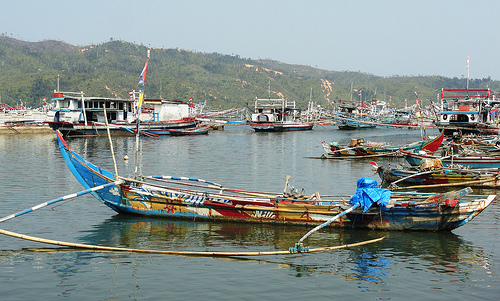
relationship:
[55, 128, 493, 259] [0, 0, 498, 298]
boat going down on water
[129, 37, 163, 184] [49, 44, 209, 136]
colorful flag on boat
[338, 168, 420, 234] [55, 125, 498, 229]
an outrigger on boat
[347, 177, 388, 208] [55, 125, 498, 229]
tarp covering portion of boat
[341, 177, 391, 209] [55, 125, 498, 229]
tarp on boat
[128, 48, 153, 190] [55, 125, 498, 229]
flag pole on boat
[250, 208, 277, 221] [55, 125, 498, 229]
word nille written on boat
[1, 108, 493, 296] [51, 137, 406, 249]
water around boat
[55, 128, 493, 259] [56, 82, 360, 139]
boat going down in background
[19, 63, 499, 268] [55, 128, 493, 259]
many boats behind boat going down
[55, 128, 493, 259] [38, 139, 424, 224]
boat going down in foreground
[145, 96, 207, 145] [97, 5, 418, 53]
hazy sky in background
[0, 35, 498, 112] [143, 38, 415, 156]
mountains covered in distance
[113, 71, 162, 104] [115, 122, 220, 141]
flag on small canoe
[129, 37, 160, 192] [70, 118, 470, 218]
flag pole on boat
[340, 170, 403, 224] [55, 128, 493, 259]
blue tarp on boat going down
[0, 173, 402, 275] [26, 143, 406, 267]
balancing rails on canoe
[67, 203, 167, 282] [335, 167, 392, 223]
reflection of tarp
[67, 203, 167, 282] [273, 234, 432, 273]
reflection in water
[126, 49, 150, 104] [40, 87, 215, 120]
flag on boat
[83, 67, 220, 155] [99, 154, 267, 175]
house boat in water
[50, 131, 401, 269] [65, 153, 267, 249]
boat has blue stripes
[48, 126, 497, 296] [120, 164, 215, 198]
boat has stripes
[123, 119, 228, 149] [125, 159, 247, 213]
boat has stripes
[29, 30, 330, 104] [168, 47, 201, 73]
mountains covered in vegetation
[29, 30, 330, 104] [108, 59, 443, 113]
mountains covered in background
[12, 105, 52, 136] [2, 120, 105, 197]
dock at edge of the water